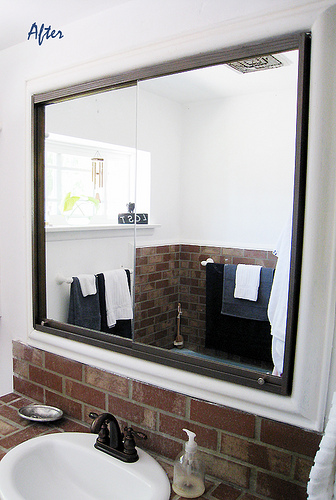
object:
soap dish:
[16, 404, 62, 421]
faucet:
[90, 410, 124, 449]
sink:
[0, 429, 171, 500]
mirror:
[35, 49, 298, 378]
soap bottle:
[172, 428, 206, 500]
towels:
[305, 401, 336, 500]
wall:
[12, 340, 336, 500]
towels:
[103, 266, 133, 326]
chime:
[92, 152, 107, 190]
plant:
[60, 191, 78, 214]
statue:
[127, 200, 136, 215]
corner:
[140, 135, 157, 171]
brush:
[173, 302, 184, 350]